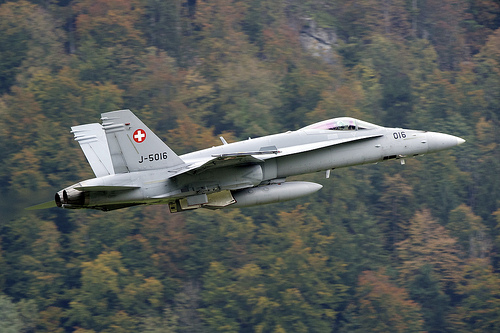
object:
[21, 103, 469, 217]
jet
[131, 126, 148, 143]
logo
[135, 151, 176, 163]
number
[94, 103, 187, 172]
tail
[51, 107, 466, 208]
military plane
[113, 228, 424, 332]
tree